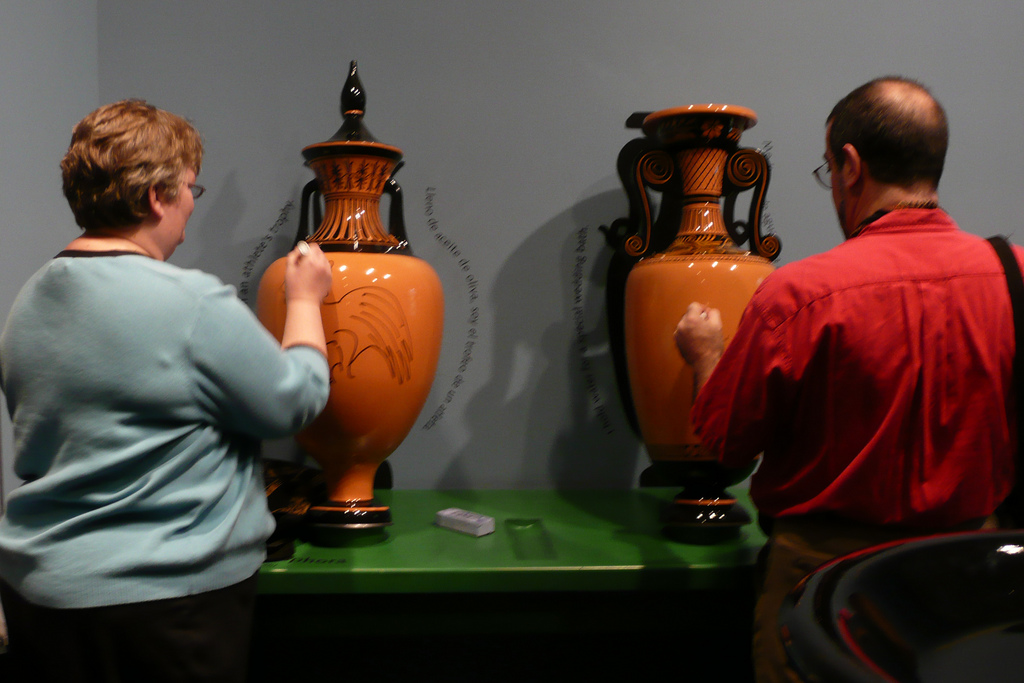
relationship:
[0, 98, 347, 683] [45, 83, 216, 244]
person with hair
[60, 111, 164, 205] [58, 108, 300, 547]
hair on woman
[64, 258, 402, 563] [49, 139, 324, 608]
shirt on woman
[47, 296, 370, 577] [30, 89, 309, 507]
shirt on woman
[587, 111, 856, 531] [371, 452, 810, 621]
pot on table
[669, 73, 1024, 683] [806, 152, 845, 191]
man wearing glasses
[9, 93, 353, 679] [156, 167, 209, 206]
person wearing glasses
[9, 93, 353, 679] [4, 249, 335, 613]
person wearing shirt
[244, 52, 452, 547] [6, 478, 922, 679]
pot on table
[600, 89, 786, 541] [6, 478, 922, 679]
pot on table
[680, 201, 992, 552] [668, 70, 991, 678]
shirt on man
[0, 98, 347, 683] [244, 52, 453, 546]
person drawing on pot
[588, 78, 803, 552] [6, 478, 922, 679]
urn on table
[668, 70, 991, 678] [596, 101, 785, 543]
man drawing on pot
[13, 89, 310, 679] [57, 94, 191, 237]
woman has hair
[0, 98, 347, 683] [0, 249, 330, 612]
person wearing shirt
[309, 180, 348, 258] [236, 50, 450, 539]
stripe on vase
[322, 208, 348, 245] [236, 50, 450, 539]
stripe on vase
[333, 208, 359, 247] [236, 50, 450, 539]
stripe on vase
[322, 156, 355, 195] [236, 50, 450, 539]
stripe on vase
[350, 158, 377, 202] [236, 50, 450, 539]
stripe on vase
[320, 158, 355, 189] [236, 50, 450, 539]
stripe on vase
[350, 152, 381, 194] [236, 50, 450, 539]
stripe on vase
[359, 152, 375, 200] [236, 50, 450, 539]
stripe on vase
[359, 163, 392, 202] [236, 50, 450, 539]
stripe on vase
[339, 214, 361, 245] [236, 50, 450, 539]
stripe on vase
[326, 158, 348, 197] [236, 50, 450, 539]
stripe on vase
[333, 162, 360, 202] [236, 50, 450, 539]
stripe on vase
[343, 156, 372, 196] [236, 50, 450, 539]
stripe on vase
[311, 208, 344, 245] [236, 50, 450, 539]
stripe on vase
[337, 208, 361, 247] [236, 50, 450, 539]
stripe on vase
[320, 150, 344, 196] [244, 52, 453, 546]
stripe on pot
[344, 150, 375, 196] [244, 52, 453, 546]
stripe on pot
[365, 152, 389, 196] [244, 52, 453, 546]
stripe on pot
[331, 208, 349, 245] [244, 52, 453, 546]
stripe on pot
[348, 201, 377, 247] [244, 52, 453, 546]
stripe on pot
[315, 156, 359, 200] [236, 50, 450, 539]
stripe on vase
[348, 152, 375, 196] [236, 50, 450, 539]
stripe on vase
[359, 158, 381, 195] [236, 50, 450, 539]
stripe on vase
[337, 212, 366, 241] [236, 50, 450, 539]
stripe on vase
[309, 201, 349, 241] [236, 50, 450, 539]
stripe on vase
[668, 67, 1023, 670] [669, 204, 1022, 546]
man wearing shirt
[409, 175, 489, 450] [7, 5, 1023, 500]
lettering on wall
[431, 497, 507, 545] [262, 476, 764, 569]
box on table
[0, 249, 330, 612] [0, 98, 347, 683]
shirt on person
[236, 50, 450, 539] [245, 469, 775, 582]
vase on table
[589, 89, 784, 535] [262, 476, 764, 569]
vase on table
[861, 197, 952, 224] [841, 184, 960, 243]
string around man's neck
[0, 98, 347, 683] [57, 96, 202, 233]
person has hair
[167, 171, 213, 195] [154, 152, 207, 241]
glasses on woman's face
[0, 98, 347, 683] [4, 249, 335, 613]
person wearing shirt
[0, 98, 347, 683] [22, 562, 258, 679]
person wearing pants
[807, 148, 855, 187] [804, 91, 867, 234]
glasses on man's face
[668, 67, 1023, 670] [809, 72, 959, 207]
man has hair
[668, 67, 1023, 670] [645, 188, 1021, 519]
man wearing shirt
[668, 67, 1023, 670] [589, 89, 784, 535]
man drawing on vase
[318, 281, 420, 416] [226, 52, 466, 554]
design on vase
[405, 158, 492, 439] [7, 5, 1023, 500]
lettering on wall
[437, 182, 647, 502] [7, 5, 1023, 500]
shadow on wall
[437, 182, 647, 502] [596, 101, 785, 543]
shadow of pot